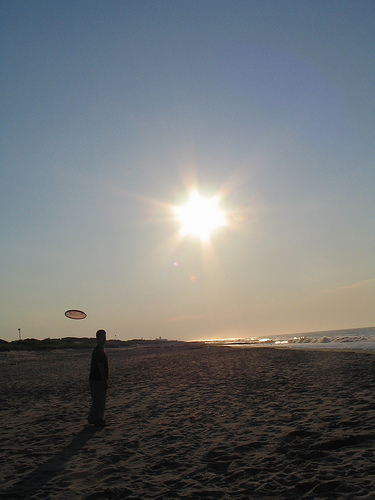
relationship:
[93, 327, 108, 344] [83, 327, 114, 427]
head of a man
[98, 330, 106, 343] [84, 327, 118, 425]
face of a man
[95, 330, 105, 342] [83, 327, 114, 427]
hair of a man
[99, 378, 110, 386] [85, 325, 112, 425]
hand of a man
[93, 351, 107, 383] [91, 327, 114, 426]
arm of a man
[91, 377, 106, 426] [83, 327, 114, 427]
leg of a man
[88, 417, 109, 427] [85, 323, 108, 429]
feet of a man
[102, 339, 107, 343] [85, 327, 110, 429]
chin of a man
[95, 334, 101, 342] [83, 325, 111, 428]
ear of a man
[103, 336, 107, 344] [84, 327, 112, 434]
nose of a man